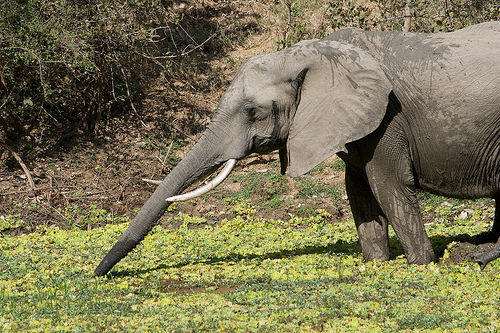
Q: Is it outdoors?
A: Yes, it is outdoors.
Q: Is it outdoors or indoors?
A: It is outdoors.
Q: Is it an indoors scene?
A: No, it is outdoors.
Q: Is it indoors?
A: No, it is outdoors.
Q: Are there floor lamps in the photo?
A: No, there are no floor lamps.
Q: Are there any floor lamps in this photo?
A: No, there are no floor lamps.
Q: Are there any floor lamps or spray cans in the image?
A: No, there are no floor lamps or spray cans.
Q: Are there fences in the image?
A: No, there are no fences.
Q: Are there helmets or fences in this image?
A: No, there are no fences or helmets.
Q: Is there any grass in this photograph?
A: Yes, there is grass.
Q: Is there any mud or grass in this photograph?
A: Yes, there is grass.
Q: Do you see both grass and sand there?
A: No, there is grass but no sand.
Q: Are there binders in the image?
A: No, there are no binders.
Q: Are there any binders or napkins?
A: No, there are no binders or napkins.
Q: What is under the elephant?
A: The grass is under the elephant.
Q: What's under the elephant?
A: The grass is under the elephant.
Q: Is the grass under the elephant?
A: Yes, the grass is under the elephant.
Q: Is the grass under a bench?
A: No, the grass is under the elephant.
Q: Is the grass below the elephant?
A: Yes, the grass is below the elephant.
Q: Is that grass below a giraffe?
A: No, the grass is below the elephant.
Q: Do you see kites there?
A: No, there are no kites.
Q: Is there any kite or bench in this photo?
A: No, there are no kites or benches.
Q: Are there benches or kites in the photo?
A: No, there are no kites or benches.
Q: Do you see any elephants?
A: Yes, there is an elephant.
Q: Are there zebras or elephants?
A: Yes, there is an elephant.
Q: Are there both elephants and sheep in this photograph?
A: No, there is an elephant but no sheep.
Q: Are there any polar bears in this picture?
A: No, there are no polar bears.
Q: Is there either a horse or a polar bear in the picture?
A: No, there are no polar bears or horses.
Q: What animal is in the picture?
A: The animal is an elephant.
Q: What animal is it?
A: The animal is an elephant.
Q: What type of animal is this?
A: This is an elephant.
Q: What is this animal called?
A: This is an elephant.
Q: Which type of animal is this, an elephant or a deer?
A: This is an elephant.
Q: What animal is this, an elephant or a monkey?
A: This is an elephant.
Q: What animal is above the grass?
A: The animal is an elephant.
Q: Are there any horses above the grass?
A: No, there is an elephant above the grass.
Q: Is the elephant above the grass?
A: Yes, the elephant is above the grass.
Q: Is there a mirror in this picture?
A: No, there are no mirrors.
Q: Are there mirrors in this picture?
A: No, there are no mirrors.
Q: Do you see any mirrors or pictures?
A: No, there are no mirrors or pictures.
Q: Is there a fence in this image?
A: No, there are no fences.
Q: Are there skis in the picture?
A: No, there are no skis.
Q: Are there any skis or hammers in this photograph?
A: No, there are no skis or hammers.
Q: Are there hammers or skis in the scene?
A: No, there are no skis or hammers.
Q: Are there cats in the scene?
A: No, there are no cats.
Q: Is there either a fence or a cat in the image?
A: No, there are no cats or fences.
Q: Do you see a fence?
A: No, there are no fences.